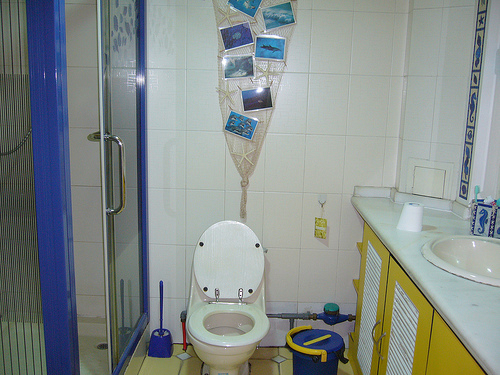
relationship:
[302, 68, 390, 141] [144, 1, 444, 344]
tiles on wall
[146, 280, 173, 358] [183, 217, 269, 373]
toilet brush beside toilet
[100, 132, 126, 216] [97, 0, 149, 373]
handle of door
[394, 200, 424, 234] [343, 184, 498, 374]
toilet paper on vanity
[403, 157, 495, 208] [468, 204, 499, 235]
toothbrush in cup